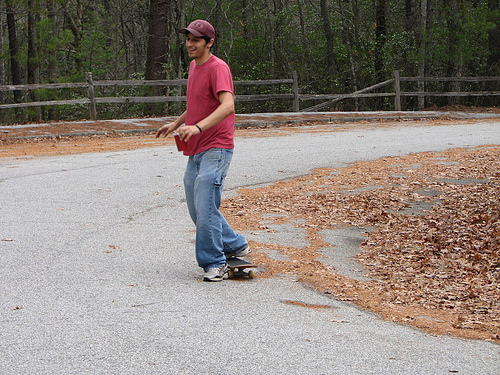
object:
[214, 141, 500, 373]
curve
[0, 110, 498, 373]
pavement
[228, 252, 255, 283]
skateboard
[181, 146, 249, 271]
blue jeans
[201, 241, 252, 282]
sneakers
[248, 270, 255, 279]
wheel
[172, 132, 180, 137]
cigarette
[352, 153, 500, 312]
brown leaves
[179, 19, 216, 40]
hat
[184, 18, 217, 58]
head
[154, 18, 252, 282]
man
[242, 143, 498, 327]
leaves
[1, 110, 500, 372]
street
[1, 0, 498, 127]
trees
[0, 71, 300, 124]
post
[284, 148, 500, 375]
spot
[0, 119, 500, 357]
sidewalk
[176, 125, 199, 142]
hand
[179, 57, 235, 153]
shirt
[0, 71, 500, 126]
fence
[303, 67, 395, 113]
piece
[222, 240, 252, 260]
foot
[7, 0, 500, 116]
background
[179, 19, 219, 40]
cap